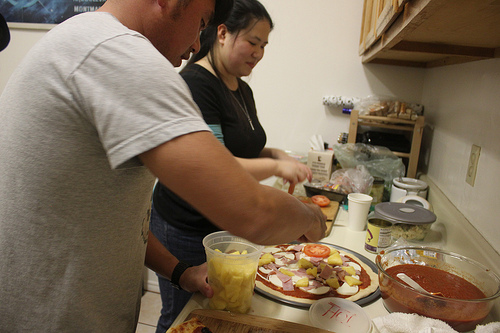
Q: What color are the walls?
A: White.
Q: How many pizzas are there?
A: One.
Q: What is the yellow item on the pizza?
A: Pineapple.